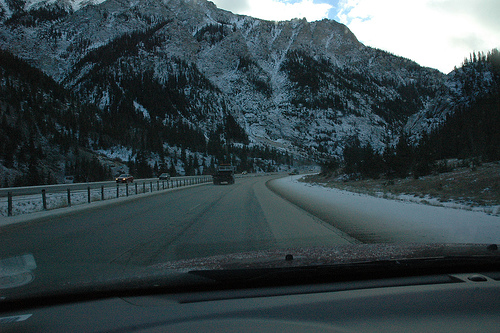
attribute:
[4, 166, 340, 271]
road —  bend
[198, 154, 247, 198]
truck — distant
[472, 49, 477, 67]
tree —  tall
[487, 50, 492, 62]
tree —  tall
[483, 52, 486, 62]
tree —  tall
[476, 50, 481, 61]
tree —  tall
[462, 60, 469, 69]
tree —  tall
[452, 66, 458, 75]
tree —  tall